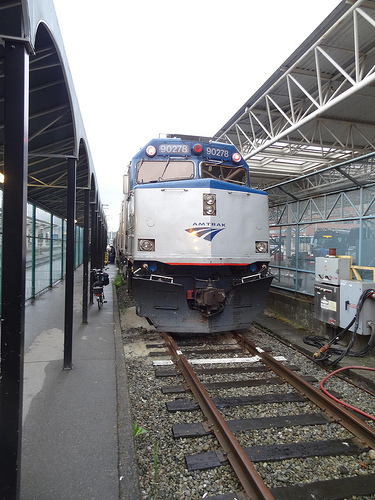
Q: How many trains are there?
A: One.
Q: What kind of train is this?
A: Amtrak.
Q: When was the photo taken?
A: Daytime.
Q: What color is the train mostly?
A: Silver.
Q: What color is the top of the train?
A: Blue.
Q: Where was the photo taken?
A: A train station.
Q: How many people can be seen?
A: None.